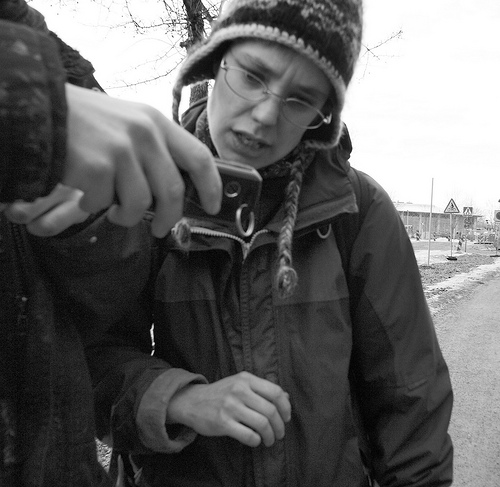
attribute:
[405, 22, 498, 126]
sky — cloudy, white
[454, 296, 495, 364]
road — pavement, grey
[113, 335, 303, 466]
arm — woman's, sticking straight out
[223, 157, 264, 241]
cell phone — black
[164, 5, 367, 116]
person — standing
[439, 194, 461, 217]
sign — triangle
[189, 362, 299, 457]
hand — stretched out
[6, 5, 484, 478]
picture — white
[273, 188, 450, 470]
winter jacket — two tone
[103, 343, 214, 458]
jacket sleeve — rolled up